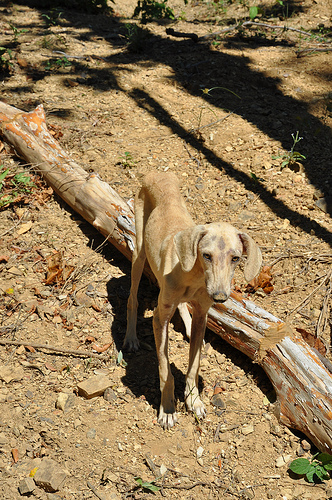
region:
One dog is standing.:
[124, 171, 246, 418]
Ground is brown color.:
[32, 380, 88, 460]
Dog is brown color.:
[139, 198, 223, 299]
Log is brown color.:
[18, 125, 125, 224]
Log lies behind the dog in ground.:
[19, 121, 167, 284]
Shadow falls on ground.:
[32, 5, 290, 117]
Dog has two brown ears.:
[175, 226, 259, 279]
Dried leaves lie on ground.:
[3, 175, 83, 309]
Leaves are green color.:
[282, 454, 329, 481]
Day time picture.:
[9, 14, 327, 492]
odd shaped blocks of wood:
[18, 373, 112, 499]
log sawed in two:
[249, 313, 301, 372]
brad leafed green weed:
[281, 437, 330, 488]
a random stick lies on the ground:
[0, 335, 110, 360]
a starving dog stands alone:
[124, 166, 263, 427]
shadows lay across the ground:
[37, 0, 329, 218]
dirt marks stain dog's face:
[173, 224, 265, 304]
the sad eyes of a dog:
[192, 247, 245, 267]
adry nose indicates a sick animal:
[207, 283, 232, 308]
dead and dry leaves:
[35, 253, 81, 311]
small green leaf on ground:
[277, 452, 326, 480]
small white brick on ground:
[76, 360, 122, 400]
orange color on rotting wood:
[287, 337, 324, 366]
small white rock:
[53, 388, 68, 405]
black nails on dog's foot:
[144, 413, 178, 429]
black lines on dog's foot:
[179, 378, 214, 414]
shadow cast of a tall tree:
[107, 69, 265, 193]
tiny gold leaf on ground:
[7, 444, 21, 458]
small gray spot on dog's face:
[204, 228, 233, 246]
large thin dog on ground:
[95, 166, 258, 417]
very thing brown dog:
[126, 162, 249, 420]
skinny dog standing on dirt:
[109, 178, 238, 422]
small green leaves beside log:
[283, 447, 329, 482]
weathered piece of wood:
[218, 284, 330, 444]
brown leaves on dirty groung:
[25, 242, 99, 302]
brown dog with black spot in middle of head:
[162, 195, 270, 331]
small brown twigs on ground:
[257, 231, 330, 326]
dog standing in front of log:
[94, 160, 271, 442]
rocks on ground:
[18, 355, 159, 499]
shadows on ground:
[75, 14, 327, 257]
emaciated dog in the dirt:
[100, 151, 276, 441]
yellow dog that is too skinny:
[109, 140, 267, 426]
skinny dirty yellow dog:
[92, 144, 264, 443]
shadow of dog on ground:
[96, 264, 196, 439]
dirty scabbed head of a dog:
[170, 215, 270, 313]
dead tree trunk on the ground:
[12, 95, 117, 250]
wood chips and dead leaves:
[23, 257, 95, 446]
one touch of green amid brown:
[272, 444, 327, 490]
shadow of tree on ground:
[106, 15, 295, 166]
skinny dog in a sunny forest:
[68, 120, 280, 444]